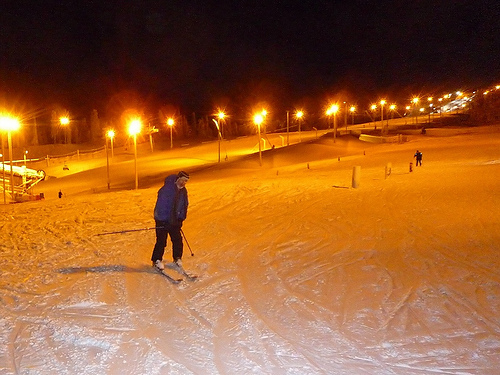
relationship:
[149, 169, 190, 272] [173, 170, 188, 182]
man wearing hat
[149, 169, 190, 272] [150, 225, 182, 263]
man wearing black pants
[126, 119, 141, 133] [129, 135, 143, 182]
light on pole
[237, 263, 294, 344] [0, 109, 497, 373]
tracks in snow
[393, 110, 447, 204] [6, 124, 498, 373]
person skiing down slope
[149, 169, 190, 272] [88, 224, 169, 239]
man holding ski pole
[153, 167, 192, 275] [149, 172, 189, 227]
man wearing jacket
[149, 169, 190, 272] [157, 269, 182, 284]
man on ski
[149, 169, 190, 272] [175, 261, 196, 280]
man on ski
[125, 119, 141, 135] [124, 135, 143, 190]
light illuminated on top of pole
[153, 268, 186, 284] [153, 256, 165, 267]
ski on foot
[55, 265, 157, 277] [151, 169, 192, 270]
shadow of man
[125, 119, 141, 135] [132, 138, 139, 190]
light on pole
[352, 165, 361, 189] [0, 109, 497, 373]
post in snow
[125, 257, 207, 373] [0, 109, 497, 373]
tracks in snow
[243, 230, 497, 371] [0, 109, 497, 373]
tracks in snow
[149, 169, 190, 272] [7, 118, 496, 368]
man skiing hill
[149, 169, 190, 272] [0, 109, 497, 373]
man skiing snow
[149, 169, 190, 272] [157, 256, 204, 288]
man on skis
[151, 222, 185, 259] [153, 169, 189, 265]
black pants on person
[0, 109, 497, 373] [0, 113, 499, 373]
snow on ground